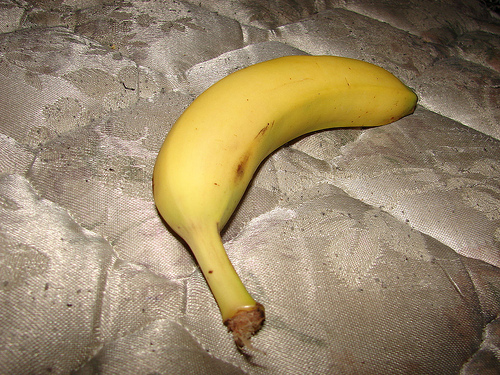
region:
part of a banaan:
[195, 222, 225, 275]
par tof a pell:
[185, 204, 240, 310]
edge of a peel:
[203, 160, 235, 226]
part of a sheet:
[383, 213, 390, 323]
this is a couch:
[302, 215, 389, 295]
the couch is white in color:
[296, 212, 430, 340]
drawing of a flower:
[53, 4, 130, 39]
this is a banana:
[143, 40, 430, 355]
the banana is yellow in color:
[285, 74, 345, 118]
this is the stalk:
[194, 245, 270, 333]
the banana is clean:
[288, 74, 323, 101]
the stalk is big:
[193, 247, 258, 319]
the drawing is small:
[327, 210, 386, 250]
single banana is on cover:
[152, 45, 422, 332]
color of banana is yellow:
[175, 38, 405, 360]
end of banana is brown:
[193, 292, 279, 353]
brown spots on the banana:
[233, 115, 281, 191]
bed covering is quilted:
[300, 187, 491, 370]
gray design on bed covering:
[40, 0, 145, 145]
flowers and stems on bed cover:
[66, 0, 206, 67]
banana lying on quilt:
[43, 5, 318, 345]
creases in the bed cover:
[325, 180, 478, 266]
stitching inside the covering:
[148, 319, 230, 372]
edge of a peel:
[201, 195, 238, 262]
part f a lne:
[382, 191, 461, 242]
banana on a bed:
[120, 37, 420, 321]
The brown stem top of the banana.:
[222, 309, 266, 353]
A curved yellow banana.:
[151, 54, 418, 348]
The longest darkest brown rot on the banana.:
[233, 154, 248, 184]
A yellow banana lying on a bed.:
[151, 54, 417, 346]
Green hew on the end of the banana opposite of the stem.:
[404, 94, 414, 113]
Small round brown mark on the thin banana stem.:
[207, 269, 213, 274]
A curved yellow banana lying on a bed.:
[151, 55, 418, 342]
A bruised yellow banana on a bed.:
[152, 54, 419, 351]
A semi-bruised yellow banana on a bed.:
[151, 55, 416, 345]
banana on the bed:
[113, 42, 431, 347]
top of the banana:
[184, 234, 285, 355]